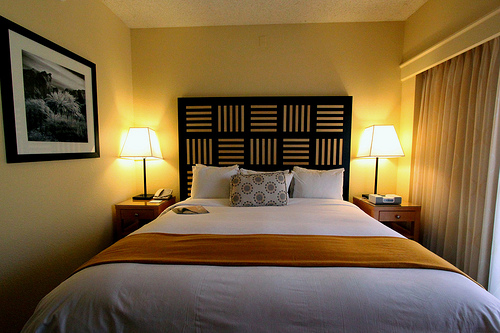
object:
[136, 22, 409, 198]
wall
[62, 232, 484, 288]
sheet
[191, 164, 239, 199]
pillow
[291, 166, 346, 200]
pillow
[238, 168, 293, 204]
pillow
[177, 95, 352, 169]
small airplane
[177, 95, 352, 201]
headboard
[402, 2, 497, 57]
wall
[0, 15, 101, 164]
artwork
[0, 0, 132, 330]
wall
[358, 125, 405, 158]
lampshade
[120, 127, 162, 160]
lampshade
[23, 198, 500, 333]
bedsheets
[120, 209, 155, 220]
brown drawer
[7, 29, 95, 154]
photograph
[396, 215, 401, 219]
knob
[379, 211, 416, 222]
drawer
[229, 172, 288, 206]
pillow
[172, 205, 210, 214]
book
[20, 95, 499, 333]
bed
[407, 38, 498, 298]
drape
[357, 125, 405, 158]
lamp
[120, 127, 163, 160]
lamp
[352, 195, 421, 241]
end table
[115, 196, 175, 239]
end table